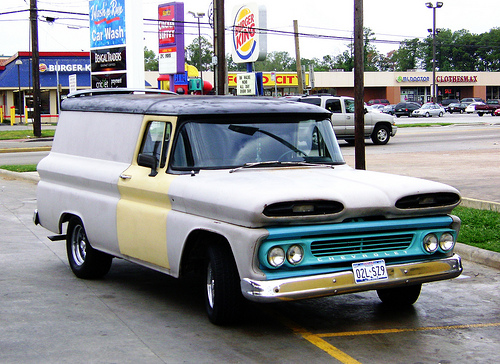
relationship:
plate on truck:
[352, 258, 389, 283] [32, 92, 463, 322]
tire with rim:
[200, 241, 242, 327] [204, 267, 215, 311]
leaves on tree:
[263, 48, 300, 73] [257, 50, 298, 72]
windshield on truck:
[189, 121, 342, 162] [32, 92, 463, 322]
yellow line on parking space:
[295, 315, 498, 361] [292, 315, 498, 362]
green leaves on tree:
[440, 31, 492, 70] [434, 32, 483, 72]